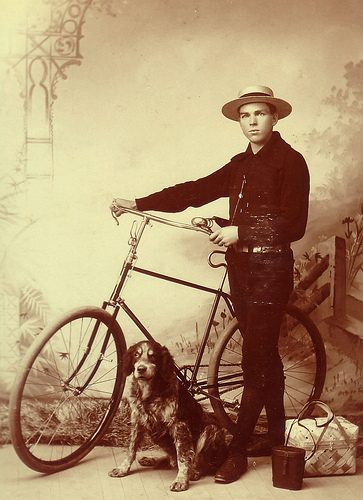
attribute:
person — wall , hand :
[111, 79, 311, 484]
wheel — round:
[7, 295, 139, 494]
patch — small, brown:
[264, 441, 306, 488]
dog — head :
[117, 345, 174, 390]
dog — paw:
[156, 479, 198, 493]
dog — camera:
[113, 320, 221, 498]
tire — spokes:
[20, 336, 106, 460]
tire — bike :
[15, 296, 129, 478]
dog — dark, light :
[107, 335, 248, 485]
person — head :
[222, 83, 291, 147]